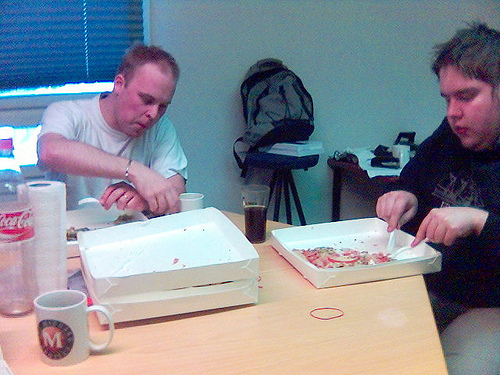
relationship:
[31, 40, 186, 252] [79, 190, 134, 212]
man holding fork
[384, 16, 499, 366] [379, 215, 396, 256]
man holding knife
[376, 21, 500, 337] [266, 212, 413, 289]
man eating pizza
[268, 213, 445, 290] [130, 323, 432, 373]
box on table